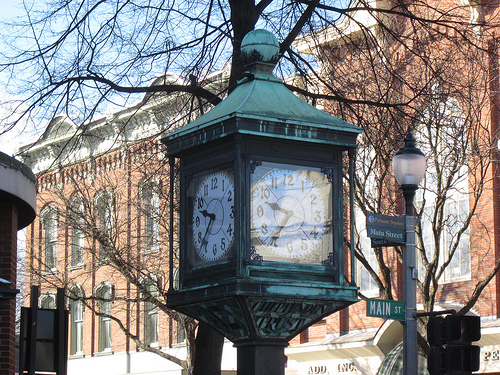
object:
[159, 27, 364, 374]
clock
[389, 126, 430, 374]
light post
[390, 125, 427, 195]
light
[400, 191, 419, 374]
pole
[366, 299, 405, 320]
sign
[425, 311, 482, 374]
walk light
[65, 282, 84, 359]
window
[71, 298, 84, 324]
pane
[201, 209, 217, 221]
hand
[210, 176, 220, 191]
number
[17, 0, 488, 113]
tree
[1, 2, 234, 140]
sky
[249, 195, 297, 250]
9:35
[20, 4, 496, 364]
building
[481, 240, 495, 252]
bricks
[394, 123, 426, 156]
top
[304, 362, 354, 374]
add. inc.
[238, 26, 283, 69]
circle